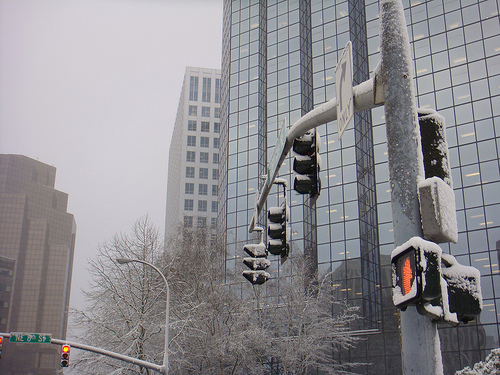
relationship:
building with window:
[216, 1, 500, 373] [239, 16, 252, 36]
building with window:
[216, 1, 500, 373] [276, 25, 291, 45]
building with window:
[216, 1, 500, 373] [247, 27, 262, 44]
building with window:
[216, 1, 500, 373] [266, 2, 279, 21]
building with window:
[216, 1, 500, 373] [286, 6, 302, 29]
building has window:
[216, 1, 500, 373] [239, 16, 252, 36]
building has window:
[216, 1, 500, 373] [247, 27, 262, 44]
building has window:
[216, 1, 500, 373] [266, 2, 279, 21]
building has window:
[216, 1, 500, 373] [276, 25, 291, 45]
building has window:
[216, 1, 500, 373] [286, 6, 302, 29]